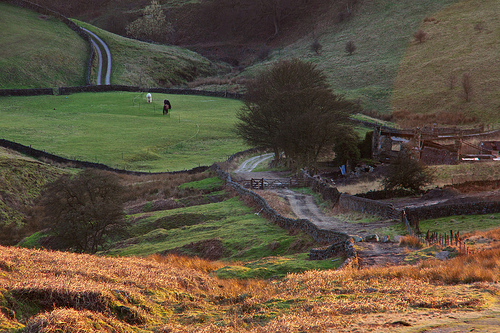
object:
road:
[73, 26, 111, 85]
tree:
[233, 58, 361, 169]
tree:
[343, 40, 357, 56]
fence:
[236, 178, 314, 188]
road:
[231, 147, 439, 274]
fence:
[215, 165, 353, 261]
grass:
[0, 244, 499, 333]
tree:
[333, 143, 364, 177]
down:
[77, 27, 112, 86]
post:
[224, 88, 228, 97]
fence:
[0, 85, 246, 102]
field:
[3, 85, 403, 174]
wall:
[296, 164, 413, 233]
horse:
[146, 93, 152, 104]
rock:
[199, 239, 225, 261]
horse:
[162, 104, 170, 116]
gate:
[251, 176, 264, 192]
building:
[371, 129, 500, 166]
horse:
[164, 99, 171, 109]